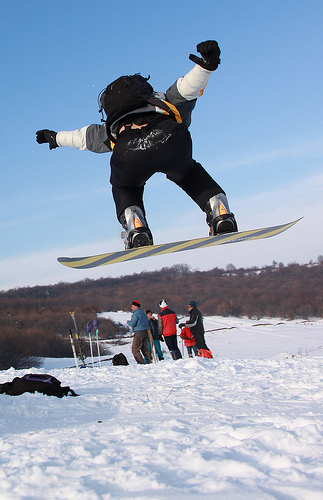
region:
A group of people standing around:
[125, 295, 221, 368]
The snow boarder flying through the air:
[13, 33, 306, 287]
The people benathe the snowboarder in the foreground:
[122, 288, 218, 363]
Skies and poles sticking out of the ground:
[63, 301, 106, 373]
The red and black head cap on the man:
[128, 298, 142, 309]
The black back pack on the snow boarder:
[98, 70, 175, 135]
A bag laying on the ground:
[2, 369, 83, 403]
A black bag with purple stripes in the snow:
[2, 369, 79, 404]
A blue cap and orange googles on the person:
[183, 298, 200, 315]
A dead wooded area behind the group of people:
[40, 269, 320, 297]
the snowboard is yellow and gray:
[167, 226, 202, 254]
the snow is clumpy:
[135, 422, 206, 469]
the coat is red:
[164, 316, 171, 332]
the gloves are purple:
[86, 315, 96, 336]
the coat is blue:
[136, 314, 144, 324]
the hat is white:
[157, 297, 168, 309]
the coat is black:
[194, 313, 201, 330]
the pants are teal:
[154, 340, 160, 350]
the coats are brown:
[136, 339, 140, 356]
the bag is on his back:
[110, 74, 168, 117]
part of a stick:
[148, 342, 158, 360]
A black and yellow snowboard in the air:
[59, 231, 297, 272]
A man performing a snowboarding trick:
[18, 44, 303, 279]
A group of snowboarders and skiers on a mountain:
[47, 57, 270, 379]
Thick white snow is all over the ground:
[105, 373, 303, 476]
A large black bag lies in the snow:
[10, 369, 78, 400]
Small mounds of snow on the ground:
[164, 358, 240, 389]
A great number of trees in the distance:
[38, 271, 311, 316]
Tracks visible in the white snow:
[104, 406, 234, 425]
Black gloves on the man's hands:
[185, 42, 235, 77]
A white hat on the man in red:
[155, 295, 172, 314]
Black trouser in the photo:
[112, 129, 216, 204]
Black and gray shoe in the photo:
[116, 211, 242, 249]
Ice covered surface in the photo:
[160, 421, 258, 476]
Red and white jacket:
[160, 307, 179, 336]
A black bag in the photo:
[6, 369, 69, 398]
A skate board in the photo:
[50, 218, 301, 272]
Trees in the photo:
[204, 269, 312, 309]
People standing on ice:
[121, 292, 211, 363]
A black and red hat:
[128, 298, 140, 306]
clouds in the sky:
[21, 181, 64, 236]